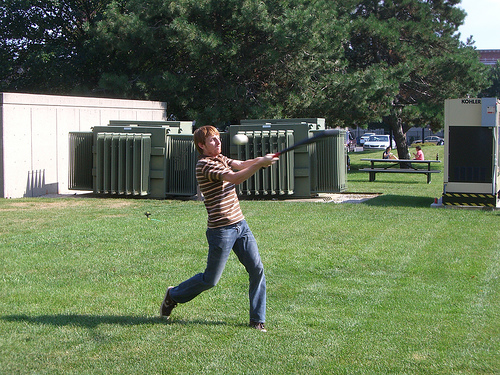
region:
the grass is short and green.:
[336, 240, 426, 326]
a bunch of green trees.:
[3, 0, 495, 117]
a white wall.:
[1, 81, 78, 151]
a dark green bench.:
[348, 139, 443, 186]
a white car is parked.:
[356, 127, 403, 153]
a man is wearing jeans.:
[207, 237, 232, 273]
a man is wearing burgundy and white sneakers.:
[148, 282, 191, 322]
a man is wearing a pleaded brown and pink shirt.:
[203, 177, 237, 228]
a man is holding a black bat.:
[264, 117, 349, 181]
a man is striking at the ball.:
[101, 110, 363, 353]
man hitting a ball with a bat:
[156, 125, 334, 327]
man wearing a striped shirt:
[186, 125, 278, 227]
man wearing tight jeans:
[161, 125, 281, 333]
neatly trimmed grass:
[43, 207, 474, 369]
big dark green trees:
[16, 3, 473, 167]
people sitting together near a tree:
[375, 139, 432, 166]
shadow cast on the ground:
[2, 300, 234, 350]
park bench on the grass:
[359, 155, 441, 182]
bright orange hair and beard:
[189, 123, 224, 160]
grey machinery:
[88, 113, 358, 199]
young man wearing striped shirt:
[149, 122, 281, 340]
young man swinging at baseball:
[152, 125, 348, 339]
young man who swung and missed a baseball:
[155, 119, 342, 334]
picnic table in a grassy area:
[350, 144, 441, 186]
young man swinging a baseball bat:
[149, 120, 341, 342]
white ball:
[228, 129, 251, 149]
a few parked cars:
[345, 126, 442, 151]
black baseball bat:
[264, 124, 351, 164]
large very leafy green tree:
[320, 0, 497, 176]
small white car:
[357, 130, 402, 157]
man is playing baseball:
[136, 82, 388, 338]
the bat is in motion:
[237, 120, 370, 195]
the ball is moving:
[213, 98, 283, 165]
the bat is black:
[253, 116, 350, 177]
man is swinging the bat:
[132, 89, 349, 194]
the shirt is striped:
[175, 132, 260, 236]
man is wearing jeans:
[130, 210, 303, 341]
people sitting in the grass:
[333, 126, 436, 182]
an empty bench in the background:
[355, 151, 440, 189]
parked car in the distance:
[340, 110, 441, 189]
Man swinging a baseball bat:
[157, 122, 326, 332]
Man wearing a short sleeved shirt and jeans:
[161, 125, 282, 334]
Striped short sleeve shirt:
[195, 151, 244, 227]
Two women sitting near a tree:
[383, 142, 426, 162]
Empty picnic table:
[360, 157, 440, 183]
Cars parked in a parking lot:
[346, 128, 400, 153]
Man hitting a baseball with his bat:
[157, 124, 329, 334]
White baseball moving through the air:
[230, 133, 251, 147]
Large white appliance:
[440, 95, 499, 210]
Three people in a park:
[155, 123, 425, 330]